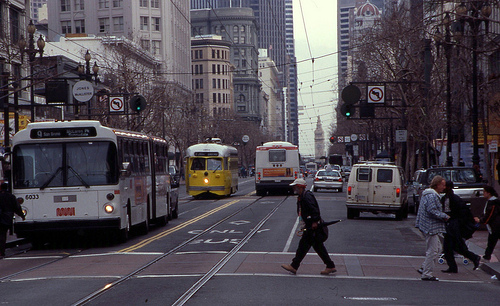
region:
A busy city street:
[19, 74, 474, 281]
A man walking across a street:
[242, 148, 353, 274]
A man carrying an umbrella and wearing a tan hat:
[275, 171, 345, 286]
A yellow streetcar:
[185, 125, 240, 201]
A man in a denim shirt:
[416, 169, 453, 276]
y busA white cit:
[8, 122, 180, 232]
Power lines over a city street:
[106, 46, 341, 126]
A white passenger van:
[336, 158, 408, 226]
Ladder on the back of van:
[354, 155, 379, 226]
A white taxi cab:
[308, 152, 345, 197]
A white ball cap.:
[290, 176, 307, 186]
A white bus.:
[12, 121, 175, 248]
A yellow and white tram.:
[181, 129, 238, 202]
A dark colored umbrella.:
[307, 218, 342, 231]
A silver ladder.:
[357, 162, 370, 207]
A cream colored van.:
[347, 157, 404, 220]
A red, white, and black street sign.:
[367, 84, 385, 103]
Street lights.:
[12, 17, 105, 83]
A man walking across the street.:
[273, 172, 348, 277]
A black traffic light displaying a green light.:
[131, 94, 148, 114]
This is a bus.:
[17, 102, 178, 257]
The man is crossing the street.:
[263, 163, 336, 305]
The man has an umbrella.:
[297, 208, 345, 240]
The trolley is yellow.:
[181, 130, 243, 209]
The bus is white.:
[23, 113, 170, 257]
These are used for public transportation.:
[8, 78, 233, 261]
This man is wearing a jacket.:
[406, 170, 447, 282]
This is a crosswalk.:
[18, 17, 450, 304]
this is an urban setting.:
[36, 12, 466, 295]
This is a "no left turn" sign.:
[368, 71, 408, 123]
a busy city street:
[9, 11, 487, 298]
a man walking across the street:
[266, 171, 347, 283]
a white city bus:
[1, 113, 181, 262]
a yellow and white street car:
[183, 126, 243, 211]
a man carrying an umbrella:
[276, 173, 346, 286]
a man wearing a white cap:
[279, 170, 312, 210]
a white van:
[343, 151, 411, 226]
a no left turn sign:
[106, 91, 126, 113]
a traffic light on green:
[336, 100, 356, 122]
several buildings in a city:
[139, 1, 293, 125]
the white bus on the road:
[7, 114, 173, 235]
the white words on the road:
[179, 224, 264, 253]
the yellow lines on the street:
[121, 189, 244, 255]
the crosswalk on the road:
[1, 239, 488, 285]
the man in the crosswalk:
[278, 173, 343, 276]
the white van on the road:
[344, 158, 409, 218]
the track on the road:
[96, 191, 288, 304]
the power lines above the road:
[123, 3, 410, 158]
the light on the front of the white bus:
[100, 200, 114, 213]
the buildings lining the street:
[4, 0, 498, 150]